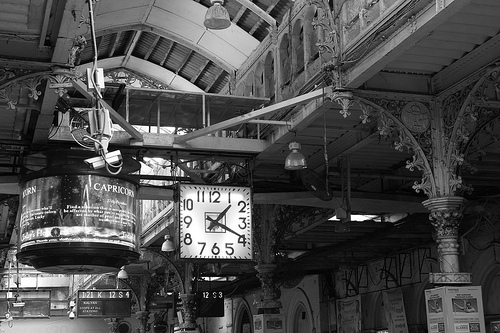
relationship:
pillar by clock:
[419, 195, 475, 287] [169, 179, 259, 269]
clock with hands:
[178, 183, 256, 265] [204, 201, 243, 239]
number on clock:
[221, 237, 235, 254] [178, 183, 256, 265]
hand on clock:
[217, 194, 251, 243] [144, 163, 264, 273]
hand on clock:
[198, 200, 258, 230] [174, 201, 256, 252]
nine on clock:
[171, 193, 206, 243] [164, 150, 313, 329]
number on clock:
[214, 235, 255, 270] [140, 157, 275, 276]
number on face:
[195, 237, 207, 257] [179, 185, 255, 259]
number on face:
[207, 188, 224, 204] [165, 176, 260, 265]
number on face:
[222, 186, 234, 205] [164, 180, 263, 270]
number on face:
[192, 184, 207, 205] [165, 176, 260, 265]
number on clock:
[174, 210, 195, 228] [178, 183, 256, 265]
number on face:
[230, 212, 252, 230] [165, 176, 260, 265]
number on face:
[234, 198, 248, 213] [165, 176, 260, 265]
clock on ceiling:
[178, 183, 256, 265] [4, 4, 374, 181]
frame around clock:
[170, 180, 185, 259] [179, 186, 252, 256]